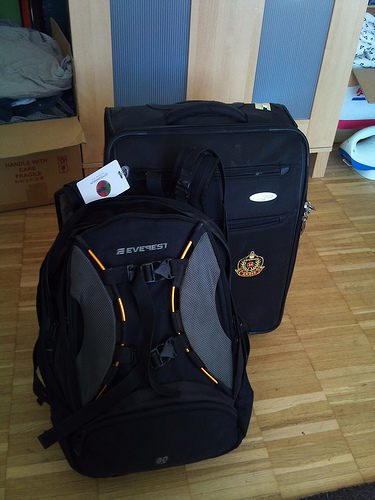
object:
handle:
[144, 100, 242, 125]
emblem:
[235, 251, 267, 279]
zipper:
[303, 200, 314, 213]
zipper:
[302, 213, 307, 232]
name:
[115, 241, 169, 255]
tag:
[76, 160, 130, 204]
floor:
[0, 160, 374, 499]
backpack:
[31, 193, 255, 477]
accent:
[85, 244, 128, 322]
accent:
[160, 230, 221, 388]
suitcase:
[93, 99, 315, 333]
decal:
[248, 190, 280, 203]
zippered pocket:
[166, 221, 234, 397]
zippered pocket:
[56, 244, 123, 419]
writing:
[6, 149, 62, 184]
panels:
[59, 209, 239, 472]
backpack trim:
[70, 232, 116, 405]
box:
[0, 114, 83, 213]